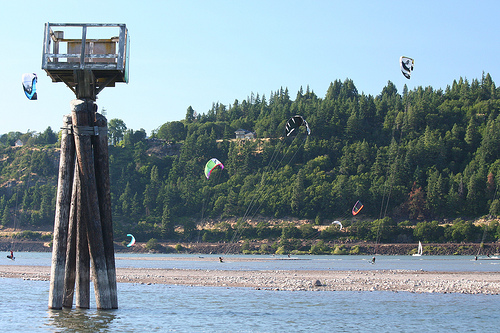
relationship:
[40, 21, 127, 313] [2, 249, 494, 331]
tower on beach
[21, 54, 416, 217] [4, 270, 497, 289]
kites over beach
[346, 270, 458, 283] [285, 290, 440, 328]
sand between water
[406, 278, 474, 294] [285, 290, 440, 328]
rocks between water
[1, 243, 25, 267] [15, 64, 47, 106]
person with a kite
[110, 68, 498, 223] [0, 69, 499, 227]
green trees on a hill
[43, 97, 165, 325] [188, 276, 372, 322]
posts in water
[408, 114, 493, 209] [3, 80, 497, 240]
trees on hill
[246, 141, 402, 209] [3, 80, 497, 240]
trees on hill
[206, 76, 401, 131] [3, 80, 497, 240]
trees on hill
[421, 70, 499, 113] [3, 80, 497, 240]
trees on hill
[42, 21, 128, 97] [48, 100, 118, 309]
stand on posts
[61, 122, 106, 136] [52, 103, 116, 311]
brace on poles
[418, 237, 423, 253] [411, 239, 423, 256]
sail on boat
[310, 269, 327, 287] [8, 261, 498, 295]
rock on ground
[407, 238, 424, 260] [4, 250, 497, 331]
windsurfer on water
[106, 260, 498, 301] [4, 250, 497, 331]
rocky sandbar in water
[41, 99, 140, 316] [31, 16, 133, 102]
poles for platform